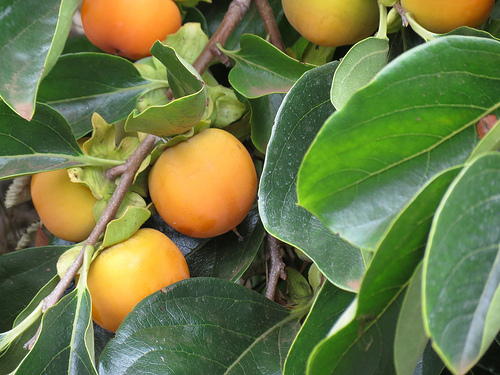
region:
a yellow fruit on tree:
[150, 127, 254, 237]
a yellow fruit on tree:
[82, 229, 189, 339]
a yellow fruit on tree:
[30, 163, 95, 236]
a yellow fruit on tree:
[76, 0, 182, 58]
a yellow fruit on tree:
[275, 0, 382, 48]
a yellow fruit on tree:
[395, 0, 490, 32]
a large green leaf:
[298, 35, 497, 249]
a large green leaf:
[418, 153, 498, 372]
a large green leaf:
[304, 162, 458, 374]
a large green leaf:
[95, 275, 302, 369]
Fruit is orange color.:
[9, 123, 238, 308]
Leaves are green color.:
[290, 269, 497, 353]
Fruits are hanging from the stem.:
[34, 2, 359, 314]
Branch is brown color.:
[76, 49, 210, 217]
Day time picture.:
[13, 10, 498, 345]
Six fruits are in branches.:
[22, 6, 472, 311]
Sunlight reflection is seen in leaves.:
[23, 75, 397, 346]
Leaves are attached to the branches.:
[136, 35, 280, 122]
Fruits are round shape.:
[48, 108, 269, 363]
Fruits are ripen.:
[51, 8, 308, 323]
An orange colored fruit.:
[138, 120, 271, 243]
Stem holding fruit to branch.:
[94, 153, 129, 194]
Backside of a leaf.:
[329, 24, 396, 119]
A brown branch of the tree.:
[85, 169, 141, 246]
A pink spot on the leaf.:
[345, 274, 365, 294]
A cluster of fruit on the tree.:
[16, 133, 281, 343]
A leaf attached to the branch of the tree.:
[207, 32, 330, 107]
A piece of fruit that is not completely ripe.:
[275, 0, 386, 50]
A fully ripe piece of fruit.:
[139, 133, 273, 241]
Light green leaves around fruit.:
[67, 115, 169, 258]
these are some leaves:
[272, 50, 490, 357]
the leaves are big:
[331, 92, 476, 262]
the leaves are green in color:
[336, 89, 466, 226]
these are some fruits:
[43, 5, 250, 290]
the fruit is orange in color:
[183, 143, 221, 188]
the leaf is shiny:
[329, 178, 367, 212]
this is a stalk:
[108, 158, 137, 178]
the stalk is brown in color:
[111, 165, 131, 177]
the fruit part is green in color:
[346, 7, 368, 28]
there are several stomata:
[290, 105, 307, 156]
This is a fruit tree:
[9, 3, 499, 340]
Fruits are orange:
[8, 101, 265, 321]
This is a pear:
[141, 115, 276, 260]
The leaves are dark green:
[279, 50, 499, 329]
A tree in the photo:
[3, 7, 499, 369]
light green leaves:
[63, 90, 189, 257]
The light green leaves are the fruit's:
[60, 70, 192, 262]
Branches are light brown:
[243, 195, 301, 300]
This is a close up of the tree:
[8, 7, 498, 367]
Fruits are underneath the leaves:
[30, 83, 264, 332]